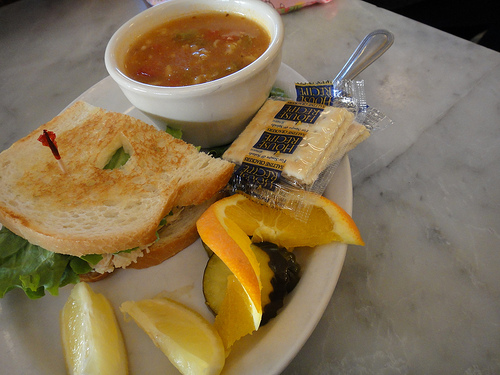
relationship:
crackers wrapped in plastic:
[221, 75, 383, 207] [223, 80, 393, 223]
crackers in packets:
[221, 75, 383, 207] [221, 80, 391, 222]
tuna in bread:
[93, 245, 151, 265] [15, 103, 225, 251]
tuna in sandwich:
[93, 245, 151, 265] [0, 98, 235, 298]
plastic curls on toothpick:
[38, 125, 58, 152] [28, 125, 75, 174]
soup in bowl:
[123, 8, 270, 79] [103, 1, 280, 128]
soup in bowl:
[123, 12, 270, 89] [93, 3, 323, 118]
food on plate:
[3, 93, 235, 310] [2, 44, 366, 373]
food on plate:
[50, 276, 132, 371] [2, 44, 366, 373]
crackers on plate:
[216, 77, 396, 224] [2, 44, 366, 373]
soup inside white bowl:
[177, 22, 244, 62] [173, 7, 295, 139]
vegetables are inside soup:
[156, 24, 257, 83] [128, 15, 268, 88]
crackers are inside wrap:
[216, 77, 396, 224] [205, 146, 352, 217]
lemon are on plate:
[49, 282, 226, 372] [2, 44, 366, 373]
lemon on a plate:
[119, 288, 233, 369] [2, 44, 366, 373]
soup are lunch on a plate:
[123, 12, 270, 89] [2, 44, 366, 373]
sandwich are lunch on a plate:
[0, 98, 235, 298] [2, 44, 366, 373]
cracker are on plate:
[224, 97, 366, 191] [2, 44, 366, 373]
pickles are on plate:
[196, 238, 302, 321] [2, 44, 366, 373]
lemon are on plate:
[60, 282, 226, 375] [28, 57, 348, 364]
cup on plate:
[100, 3, 289, 141] [2, 44, 366, 373]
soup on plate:
[123, 8, 270, 79] [2, 44, 366, 373]